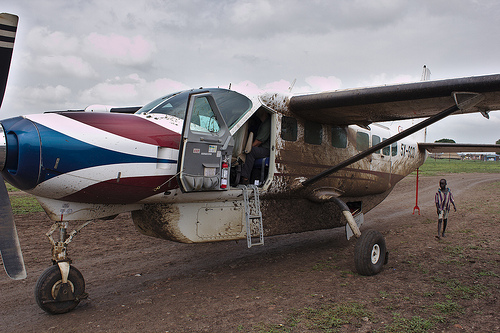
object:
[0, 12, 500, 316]
plane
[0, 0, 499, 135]
sky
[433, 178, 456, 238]
boy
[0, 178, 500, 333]
ground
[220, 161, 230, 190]
extinguisher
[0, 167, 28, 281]
propellers